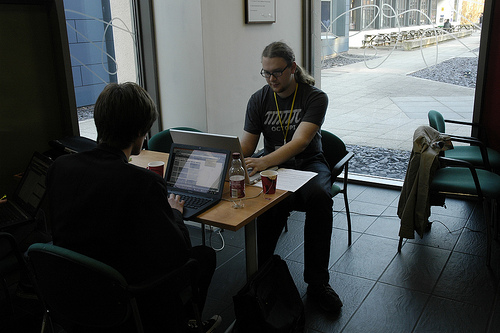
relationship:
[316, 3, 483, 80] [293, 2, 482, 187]
graphics on window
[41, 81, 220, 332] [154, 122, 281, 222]
man using laptop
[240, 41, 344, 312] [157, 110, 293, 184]
man using laptop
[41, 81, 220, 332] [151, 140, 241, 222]
man typing on laptop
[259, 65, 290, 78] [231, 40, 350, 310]
glasses on face of man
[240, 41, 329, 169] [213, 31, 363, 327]
man/lanyard on neck of man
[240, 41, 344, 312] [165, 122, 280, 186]
man using laptop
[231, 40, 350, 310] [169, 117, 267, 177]
man using laptop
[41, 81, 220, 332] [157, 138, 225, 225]
man using laptop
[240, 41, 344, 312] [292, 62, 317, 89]
man has ponytail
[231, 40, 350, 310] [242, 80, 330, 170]
man wearing shirt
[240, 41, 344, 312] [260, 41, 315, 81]
man has long hair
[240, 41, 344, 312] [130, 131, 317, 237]
man at table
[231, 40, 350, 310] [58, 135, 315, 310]
man at table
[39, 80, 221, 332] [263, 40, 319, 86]
man has long hair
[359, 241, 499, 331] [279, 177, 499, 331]
tiles on floor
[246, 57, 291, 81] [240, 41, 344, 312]
glasses on man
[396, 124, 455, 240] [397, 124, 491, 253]
jacket on chair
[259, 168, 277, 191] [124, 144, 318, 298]
cup on table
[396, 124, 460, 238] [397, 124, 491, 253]
jacket on chair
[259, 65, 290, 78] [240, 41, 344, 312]
glasses on man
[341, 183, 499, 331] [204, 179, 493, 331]
tiles on floor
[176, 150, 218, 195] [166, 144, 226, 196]
reflection on screen